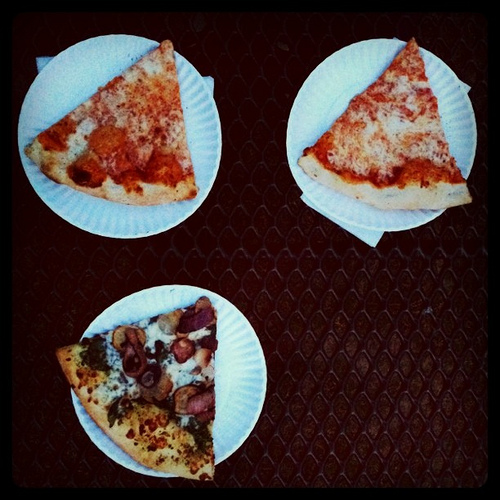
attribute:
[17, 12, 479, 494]
table — red, stained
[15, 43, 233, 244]
plate — paper, white, round, used, disposable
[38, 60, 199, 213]
pizza — cheese, sliced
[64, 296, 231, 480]
pizza — sliced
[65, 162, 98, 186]
bubble — brown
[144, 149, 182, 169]
sauce — red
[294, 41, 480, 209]
pizza — sliced